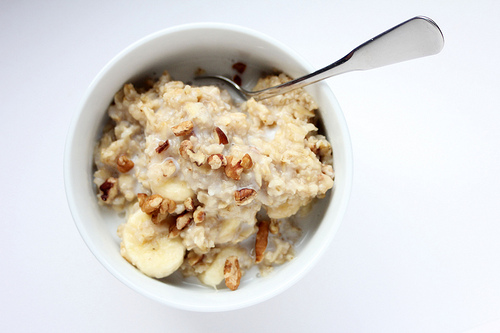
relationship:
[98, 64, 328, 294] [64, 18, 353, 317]
oatmeal in bowl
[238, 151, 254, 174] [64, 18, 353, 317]
nut in bowl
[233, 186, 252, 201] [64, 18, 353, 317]
nut in bowl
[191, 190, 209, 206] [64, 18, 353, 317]
nut in bowl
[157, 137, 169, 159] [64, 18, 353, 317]
nut in bowl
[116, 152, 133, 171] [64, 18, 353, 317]
nut in bowl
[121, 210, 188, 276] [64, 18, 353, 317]
banana in bowl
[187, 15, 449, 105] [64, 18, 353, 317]
spoon in bowl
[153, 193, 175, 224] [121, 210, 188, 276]
walnut in top of banana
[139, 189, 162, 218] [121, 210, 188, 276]
walnut in top of banana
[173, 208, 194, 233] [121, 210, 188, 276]
walnut in top of banana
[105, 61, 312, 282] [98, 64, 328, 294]
milk for oatmeal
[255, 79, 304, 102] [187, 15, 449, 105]
reflection in spoon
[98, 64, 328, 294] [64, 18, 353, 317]
oatmeal inside bowl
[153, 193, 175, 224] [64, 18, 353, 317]
walnut in bowl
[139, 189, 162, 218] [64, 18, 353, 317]
walnut in bowl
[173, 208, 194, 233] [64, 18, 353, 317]
walnut in bowl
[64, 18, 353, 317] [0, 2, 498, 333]
bowl on top of table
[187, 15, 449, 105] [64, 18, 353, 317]
spoon sticking out of bowl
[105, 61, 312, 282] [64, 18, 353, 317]
milk in bowl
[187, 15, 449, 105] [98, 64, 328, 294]
spoon stuck in oatmeal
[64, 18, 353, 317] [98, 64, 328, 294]
bowl with oatmeal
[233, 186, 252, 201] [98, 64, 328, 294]
nut over oatmeal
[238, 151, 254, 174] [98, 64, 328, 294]
nut over oatmeal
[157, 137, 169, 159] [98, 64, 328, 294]
nut over oatmeal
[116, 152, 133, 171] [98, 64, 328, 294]
nut over oatmeal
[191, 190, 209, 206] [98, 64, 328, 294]
nut over oatmeal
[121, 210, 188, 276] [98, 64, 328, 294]
banana ni oatmeal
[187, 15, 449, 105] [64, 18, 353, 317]
spoon inside bowl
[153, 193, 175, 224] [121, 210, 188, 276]
walnut next to banana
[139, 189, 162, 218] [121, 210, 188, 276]
walnut next to banana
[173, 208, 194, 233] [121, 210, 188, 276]
walnut next to banana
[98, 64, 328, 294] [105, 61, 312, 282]
oatmeal with milk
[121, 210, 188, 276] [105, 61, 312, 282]
banana over milk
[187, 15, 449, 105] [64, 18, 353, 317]
spoon dipped in bowl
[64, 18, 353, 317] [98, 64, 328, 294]
bowl filled with oatmeal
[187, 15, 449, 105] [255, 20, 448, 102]
spoon has handle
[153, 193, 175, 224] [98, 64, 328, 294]
walnut in oatmeal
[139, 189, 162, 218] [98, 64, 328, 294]
walnut in oatmeal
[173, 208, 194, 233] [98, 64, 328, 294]
walnut in oatmeal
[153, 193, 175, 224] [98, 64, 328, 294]
walnut on top of oatmeal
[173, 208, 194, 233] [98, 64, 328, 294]
walnut on top of oatmeal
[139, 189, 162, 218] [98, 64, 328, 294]
walnut on top of oatmeal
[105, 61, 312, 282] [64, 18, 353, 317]
milk inside bowl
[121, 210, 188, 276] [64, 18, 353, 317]
banana inside bowl